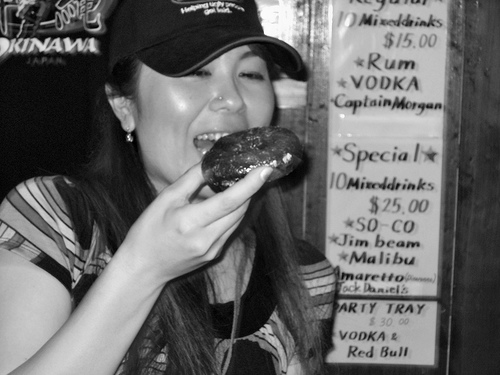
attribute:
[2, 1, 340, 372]
woman — eat.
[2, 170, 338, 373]
shirt — striped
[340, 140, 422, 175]
word — handwritten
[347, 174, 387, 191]
word — handwritten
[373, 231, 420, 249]
word — handwritten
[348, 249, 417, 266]
word — handwritten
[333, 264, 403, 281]
word — handwritten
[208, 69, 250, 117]
nose — woman's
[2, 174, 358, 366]
shirt — striped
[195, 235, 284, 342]
shirt collar — solid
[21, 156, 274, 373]
hand — girl's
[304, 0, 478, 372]
sign — white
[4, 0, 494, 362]
black photograph — white, woman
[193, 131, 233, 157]
woman's teeth — womens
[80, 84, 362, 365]
her hair — hanging down.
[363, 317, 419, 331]
party tray price — price 